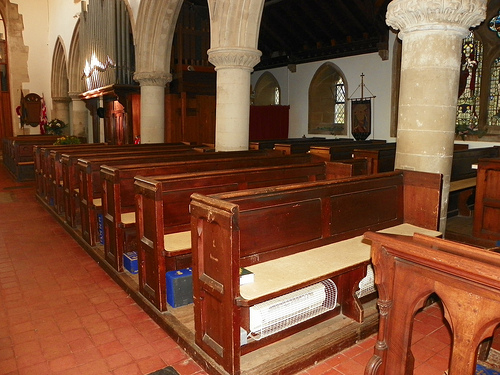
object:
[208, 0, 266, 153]
column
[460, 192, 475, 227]
ground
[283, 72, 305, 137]
wall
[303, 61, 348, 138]
window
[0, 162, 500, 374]
floor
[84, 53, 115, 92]
light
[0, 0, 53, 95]
wall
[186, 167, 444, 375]
bench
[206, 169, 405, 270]
panels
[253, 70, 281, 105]
arch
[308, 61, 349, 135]
arch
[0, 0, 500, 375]
building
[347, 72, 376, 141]
banner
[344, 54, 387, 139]
wall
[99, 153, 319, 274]
bench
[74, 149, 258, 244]
bench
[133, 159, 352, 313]
bench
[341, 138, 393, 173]
bench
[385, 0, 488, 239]
column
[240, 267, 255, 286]
book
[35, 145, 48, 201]
bench side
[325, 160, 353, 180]
bench side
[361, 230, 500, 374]
decoration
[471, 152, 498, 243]
pew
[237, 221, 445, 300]
cushion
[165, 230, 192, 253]
cushion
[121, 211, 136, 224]
cushion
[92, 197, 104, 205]
cushion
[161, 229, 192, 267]
seats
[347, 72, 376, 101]
cross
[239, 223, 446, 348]
seat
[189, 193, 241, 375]
side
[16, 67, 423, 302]
place